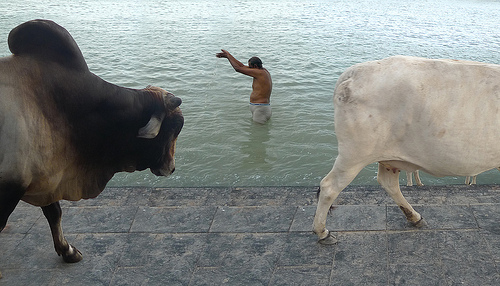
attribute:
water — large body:
[5, 0, 487, 189]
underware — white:
[234, 88, 292, 133]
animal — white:
[292, 47, 499, 246]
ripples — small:
[172, 65, 204, 86]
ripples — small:
[277, 36, 317, 95]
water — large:
[171, 128, 248, 165]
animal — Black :
[4, 11, 205, 266]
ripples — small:
[257, 140, 337, 167]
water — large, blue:
[312, 9, 483, 53]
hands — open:
[212, 45, 231, 61]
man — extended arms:
[211, 45, 276, 124]